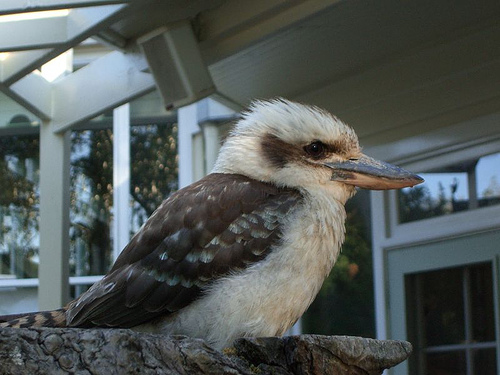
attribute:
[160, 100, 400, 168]
wall — thick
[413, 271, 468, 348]
pane — black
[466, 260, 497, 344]
pane — black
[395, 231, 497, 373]
window — big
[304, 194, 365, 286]
breast — feathered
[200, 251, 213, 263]
feathers — white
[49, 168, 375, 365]
wing — feathered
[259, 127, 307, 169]
spot — brown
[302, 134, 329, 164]
eye — black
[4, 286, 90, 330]
tail — brown, black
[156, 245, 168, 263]
feathers — white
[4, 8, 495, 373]
building — white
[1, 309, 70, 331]
tail — striped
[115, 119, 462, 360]
feather — white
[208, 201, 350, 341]
underbelly — white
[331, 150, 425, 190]
beak — short, thick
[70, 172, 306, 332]
wing — brown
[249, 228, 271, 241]
spot — white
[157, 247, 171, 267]
spot — white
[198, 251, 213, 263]
spot — white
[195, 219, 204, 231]
spot — white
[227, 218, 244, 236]
spot — white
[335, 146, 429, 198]
beak — large